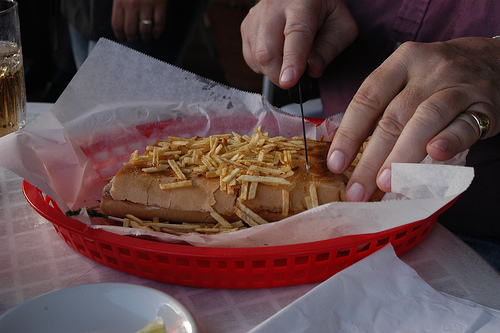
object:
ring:
[464, 109, 491, 142]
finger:
[424, 100, 497, 162]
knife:
[295, 78, 313, 177]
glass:
[0, 0, 28, 139]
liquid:
[0, 39, 26, 137]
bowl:
[0, 280, 200, 333]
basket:
[21, 109, 463, 290]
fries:
[155, 179, 193, 191]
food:
[100, 122, 397, 235]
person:
[238, 0, 500, 203]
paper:
[0, 35, 478, 248]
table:
[0, 102, 499, 333]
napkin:
[242, 240, 500, 333]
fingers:
[238, 0, 359, 90]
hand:
[325, 34, 500, 202]